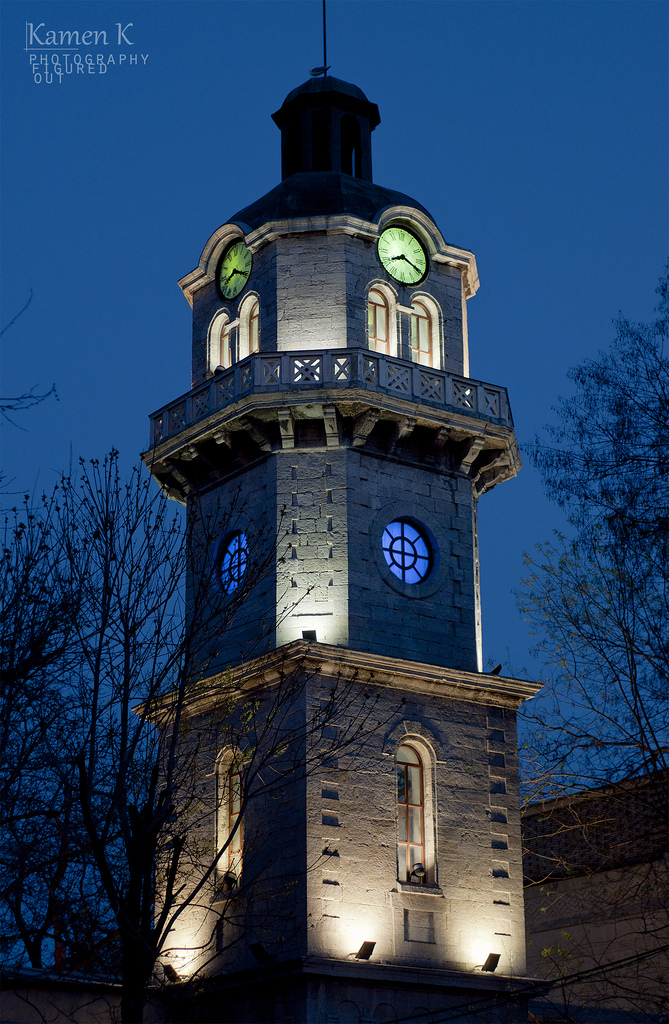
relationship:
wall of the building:
[329, 716, 511, 951] [171, 98, 538, 1002]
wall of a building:
[305, 655, 528, 986] [171, 98, 538, 1002]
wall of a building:
[305, 655, 528, 986] [146, 85, 516, 1021]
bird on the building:
[301, 53, 337, 82] [132, 0, 543, 1024]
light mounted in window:
[351, 925, 378, 962] [385, 738, 440, 914]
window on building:
[395, 733, 439, 894] [129, 79, 546, 1021]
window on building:
[365, 499, 451, 598] [129, 79, 546, 1021]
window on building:
[204, 512, 263, 605] [129, 79, 546, 1021]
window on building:
[230, 286, 264, 362] [129, 79, 546, 1021]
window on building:
[202, 302, 231, 376] [129, 79, 546, 1021]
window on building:
[361, 276, 401, 357] [129, 79, 546, 1021]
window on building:
[404, 286, 445, 371] [129, 79, 546, 1021]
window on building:
[205, 737, 251, 906] [129, 79, 546, 1021]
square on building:
[319, 868, 343, 888] [129, 79, 546, 1021]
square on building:
[318, 831, 345, 861] [129, 79, 546, 1021]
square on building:
[318, 808, 343, 828] [129, 79, 546, 1021]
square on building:
[319, 776, 343, 802] [129, 79, 546, 1021]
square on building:
[319, 750, 343, 773] [129, 79, 546, 1021]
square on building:
[487, 857, 512, 882] [129, 79, 546, 1021]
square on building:
[487, 829, 513, 854] [129, 79, 546, 1021]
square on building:
[483, 769, 509, 798] [129, 79, 546, 1021]